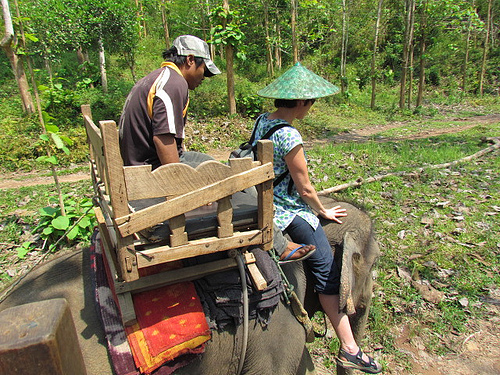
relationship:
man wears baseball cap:
[119, 33, 317, 265] [171, 33, 221, 77]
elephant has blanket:
[0, 192, 396, 373] [195, 245, 282, 330]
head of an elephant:
[333, 222, 380, 338] [241, 203, 394, 341]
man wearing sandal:
[119, 33, 317, 265] [276, 242, 316, 264]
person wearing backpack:
[250, 61, 384, 374] [219, 144, 266, 210]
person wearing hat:
[250, 61, 384, 374] [256, 61, 343, 100]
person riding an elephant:
[251, 91, 381, 370] [0, 192, 396, 373]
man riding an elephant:
[119, 33, 317, 265] [0, 192, 396, 373]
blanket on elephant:
[98, 240, 213, 373] [0, 192, 396, 373]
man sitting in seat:
[116, 32, 222, 181] [76, 99, 276, 296]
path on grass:
[8, 119, 479, 200] [1, 85, 498, 373]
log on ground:
[332, 139, 496, 188] [351, 186, 484, 195]